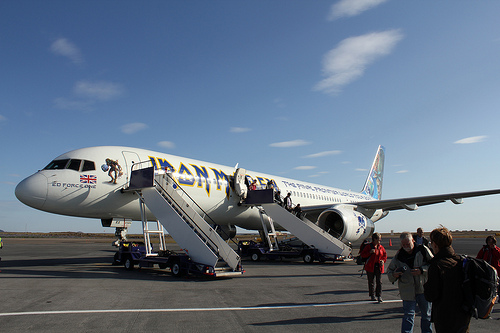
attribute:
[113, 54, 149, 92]
sky — blue, clear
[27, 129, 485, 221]
plane — white, large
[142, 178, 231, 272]
steps — white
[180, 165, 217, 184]
logo — blue, iron maiden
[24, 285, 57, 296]
ground — gray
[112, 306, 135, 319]
line — white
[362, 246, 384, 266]
jacket — red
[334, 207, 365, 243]
engine — big, large